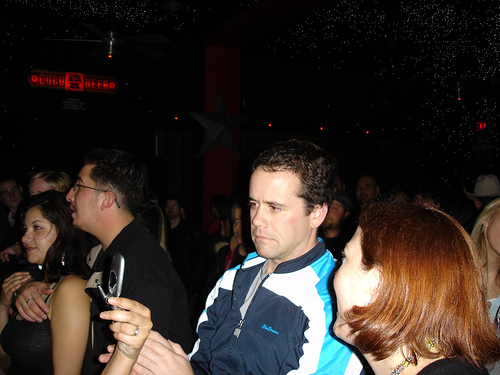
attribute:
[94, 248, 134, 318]
flip phone — silver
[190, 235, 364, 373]
coat — white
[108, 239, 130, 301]
phone — silver, flip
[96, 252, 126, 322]
flip phone — silver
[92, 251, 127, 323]
phone — silver, flip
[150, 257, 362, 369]
coat — dark blue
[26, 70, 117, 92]
sign — red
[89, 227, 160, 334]
flip phone — silver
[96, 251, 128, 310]
phone — silver, flip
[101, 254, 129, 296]
phone — silver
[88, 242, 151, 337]
phone — silver, flip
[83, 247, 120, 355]
flip phone — silver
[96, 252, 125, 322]
phone — flip, silver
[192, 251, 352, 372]
coat — light blue